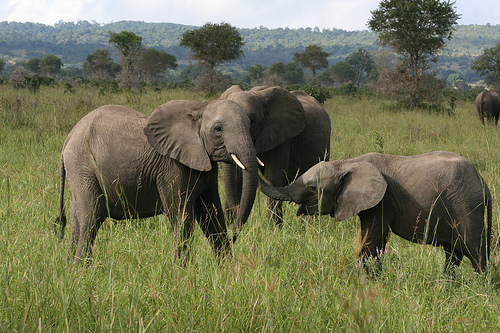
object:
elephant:
[50, 98, 264, 269]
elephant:
[218, 83, 332, 244]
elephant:
[251, 150, 493, 276]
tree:
[366, 1, 461, 113]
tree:
[181, 20, 243, 96]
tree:
[106, 31, 143, 91]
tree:
[292, 44, 329, 80]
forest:
[1, 29, 499, 98]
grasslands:
[1, 104, 499, 331]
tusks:
[231, 153, 265, 169]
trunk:
[229, 153, 259, 234]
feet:
[67, 210, 103, 271]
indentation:
[80, 108, 103, 163]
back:
[76, 103, 148, 143]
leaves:
[443, 31, 455, 41]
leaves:
[215, 36, 225, 42]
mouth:
[290, 197, 310, 217]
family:
[50, 84, 492, 282]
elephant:
[470, 89, 499, 127]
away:
[472, 88, 498, 128]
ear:
[140, 99, 212, 173]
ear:
[254, 86, 309, 155]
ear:
[330, 158, 388, 223]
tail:
[50, 146, 72, 244]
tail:
[482, 181, 492, 262]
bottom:
[386, 56, 448, 111]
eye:
[213, 124, 224, 133]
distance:
[1, 2, 498, 82]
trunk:
[255, 176, 301, 204]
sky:
[1, 1, 499, 20]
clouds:
[11, 1, 79, 23]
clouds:
[310, 3, 354, 28]